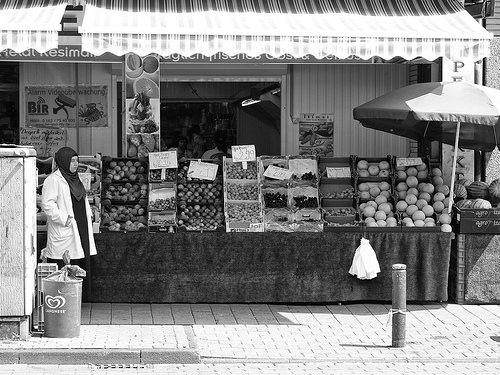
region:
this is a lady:
[43, 147, 97, 259]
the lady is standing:
[41, 145, 101, 259]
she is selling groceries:
[149, 157, 344, 229]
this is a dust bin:
[37, 267, 84, 347]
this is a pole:
[392, 258, 411, 356]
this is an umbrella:
[401, 85, 456, 124]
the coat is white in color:
[48, 183, 70, 217]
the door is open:
[171, 80, 284, 141]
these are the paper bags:
[348, 239, 382, 280]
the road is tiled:
[278, 307, 330, 347]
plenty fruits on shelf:
[125, 152, 309, 277]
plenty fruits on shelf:
[95, 111, 255, 226]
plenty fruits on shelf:
[160, 150, 274, 247]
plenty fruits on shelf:
[150, 135, 250, 206]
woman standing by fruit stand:
[48, 142, 124, 267]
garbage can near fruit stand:
[39, 260, 111, 355]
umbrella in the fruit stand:
[354, 66, 492, 231]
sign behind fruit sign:
[20, 77, 135, 141]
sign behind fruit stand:
[295, 102, 353, 162]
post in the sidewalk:
[385, 261, 424, 368]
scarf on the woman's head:
[57, 145, 97, 207]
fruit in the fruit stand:
[355, 152, 392, 231]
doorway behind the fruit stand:
[168, 68, 279, 150]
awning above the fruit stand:
[80, 6, 487, 61]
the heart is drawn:
[53, 297, 65, 308]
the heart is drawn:
[50, 294, 60, 306]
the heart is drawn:
[42, 294, 59, 311]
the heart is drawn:
[47, 286, 59, 308]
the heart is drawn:
[47, 300, 62, 310]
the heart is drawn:
[52, 296, 73, 322]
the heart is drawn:
[56, 299, 68, 314]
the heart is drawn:
[46, 291, 64, 314]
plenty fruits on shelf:
[168, 190, 395, 274]